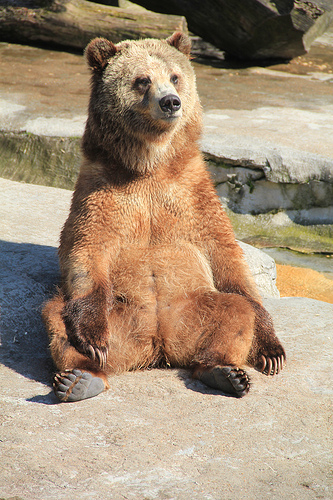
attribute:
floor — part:
[29, 418, 237, 497]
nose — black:
[159, 93, 180, 114]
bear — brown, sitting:
[41, 26, 289, 408]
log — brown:
[0, 1, 192, 65]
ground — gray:
[2, 32, 333, 498]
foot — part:
[52, 365, 109, 404]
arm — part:
[57, 169, 119, 355]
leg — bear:
[42, 289, 144, 379]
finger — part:
[86, 338, 95, 360]